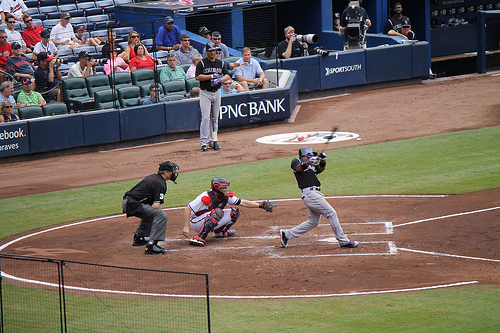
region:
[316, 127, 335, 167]
The bat the batter is swinging.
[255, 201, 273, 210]
The glove the catcher is wearing.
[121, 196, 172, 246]
The gray pants the umpire is wearing.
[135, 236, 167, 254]
The shoes the umpire is wearing.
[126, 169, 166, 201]
The black shirt the umpire is wearing.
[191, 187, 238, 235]
The baseball uniform the catcher is wearing.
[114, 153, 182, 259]
the umpire wearing black clothes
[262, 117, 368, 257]
batter with a black bat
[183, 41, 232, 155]
player stand on side the field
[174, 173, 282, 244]
the catcher is crouched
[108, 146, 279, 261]
the umpire is behind the catcher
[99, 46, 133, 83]
person with pink top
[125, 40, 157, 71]
person with red top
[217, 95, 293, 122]
advertisement for the PNC Bank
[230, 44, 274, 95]
man with blue shirt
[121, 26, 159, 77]
women wearing orange top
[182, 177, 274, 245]
A catcher kneeling down in black and red head gear.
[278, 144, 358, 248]
A batter in grey pants.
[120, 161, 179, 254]
An umpire leaning down in black head gear.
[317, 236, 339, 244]
A white home base.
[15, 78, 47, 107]
Man in green shirt sitting with black and red hat on.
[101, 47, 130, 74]
Woman in pink sitting with sunglasses on.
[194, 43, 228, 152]
Player in black shirt standing by a wall.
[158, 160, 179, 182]
Black head gear on an umpire.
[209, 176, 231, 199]
Black and red head gear.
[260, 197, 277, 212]
Black glove on a man's left hand.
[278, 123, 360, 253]
Baseball player swinging at ball with bat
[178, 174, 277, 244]
Baseball catcher sitting in playing position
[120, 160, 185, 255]
Umpire standing behind catcher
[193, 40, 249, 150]
Baseball player waiting for his turn at bat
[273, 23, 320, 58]
Cameraman working at baseball game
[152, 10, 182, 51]
Man wearing blue shirt watching baseball game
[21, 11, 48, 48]
Man wearing red shirt and sunglasses watching baseball game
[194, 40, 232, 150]
Baseball player wearing gray and black uniform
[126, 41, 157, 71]
Lady wearing short sleeve red shirt watching baseball game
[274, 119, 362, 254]
Batter swinging at baseball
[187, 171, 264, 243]
Catcher in a baseball game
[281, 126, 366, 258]
Man swinging a bat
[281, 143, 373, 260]
Man playing baseball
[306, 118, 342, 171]
Bat swinging in the air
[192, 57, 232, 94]
Black shirt on a baseball player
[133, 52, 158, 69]
Red shirt on a woman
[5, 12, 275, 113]
People sitting in bleachers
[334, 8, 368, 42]
Camera watching baseball players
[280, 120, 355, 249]
baseball player post bat swing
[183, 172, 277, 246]
squatting baseball player wearing red protective gear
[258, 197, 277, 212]
worn black catcher's glove